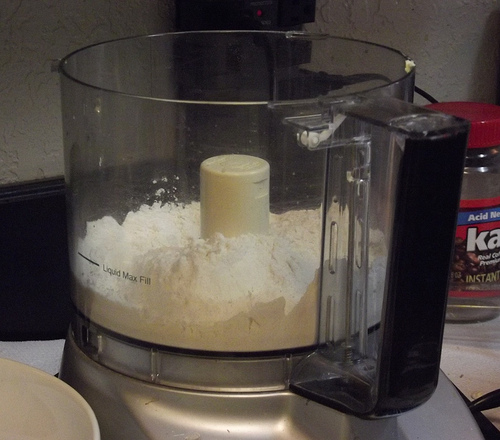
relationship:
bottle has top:
[420, 101, 499, 326] [428, 100, 484, 143]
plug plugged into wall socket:
[274, 62, 344, 102] [218, 27, 299, 116]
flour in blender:
[55, 162, 390, 354] [39, 16, 484, 436]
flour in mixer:
[72, 201, 390, 355] [53, 27, 499, 438]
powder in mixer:
[58, 157, 395, 352] [54, 25, 443, 417]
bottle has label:
[417, 97, 499, 329] [449, 195, 499, 297]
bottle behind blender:
[420, 101, 499, 326] [108, 54, 496, 386]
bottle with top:
[420, 101, 499, 326] [417, 100, 497, 152]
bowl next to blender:
[0, 352, 102, 437] [39, 16, 484, 436]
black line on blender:
[76, 252, 99, 267] [64, 50, 482, 437]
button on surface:
[255, 9, 262, 17] [191, 2, 307, 36]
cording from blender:
[477, 390, 484, 408] [64, 50, 482, 437]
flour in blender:
[72, 201, 390, 355] [39, 16, 484, 436]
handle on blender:
[287, 95, 465, 419] [39, 16, 484, 436]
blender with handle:
[39, 16, 484, 436] [287, 95, 465, 419]